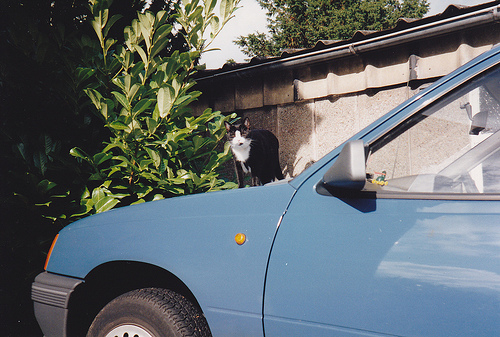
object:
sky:
[226, 12, 261, 46]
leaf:
[157, 82, 177, 121]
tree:
[69, 0, 248, 219]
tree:
[233, 1, 433, 63]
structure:
[182, 0, 500, 188]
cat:
[224, 118, 288, 189]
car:
[30, 42, 499, 336]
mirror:
[320, 137, 366, 192]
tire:
[82, 285, 212, 336]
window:
[366, 60, 500, 195]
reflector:
[234, 230, 248, 244]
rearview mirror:
[459, 102, 490, 137]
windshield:
[409, 144, 500, 183]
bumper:
[30, 270, 85, 336]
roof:
[187, 0, 499, 82]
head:
[223, 117, 253, 148]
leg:
[233, 157, 247, 189]